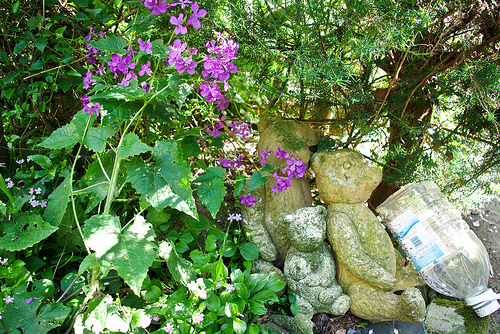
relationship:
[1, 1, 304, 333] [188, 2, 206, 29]
plant with flower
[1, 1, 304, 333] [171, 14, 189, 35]
plant with flower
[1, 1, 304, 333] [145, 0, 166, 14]
plant with flower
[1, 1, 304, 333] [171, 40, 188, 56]
plant with flower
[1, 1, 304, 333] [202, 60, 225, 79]
plant with flower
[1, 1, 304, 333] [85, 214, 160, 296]
plant with leaf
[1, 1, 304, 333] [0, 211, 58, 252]
plant with leaf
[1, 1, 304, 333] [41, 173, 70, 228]
plant with leaf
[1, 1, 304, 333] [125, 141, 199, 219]
plant with leaf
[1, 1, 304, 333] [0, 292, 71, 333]
plant with leaf